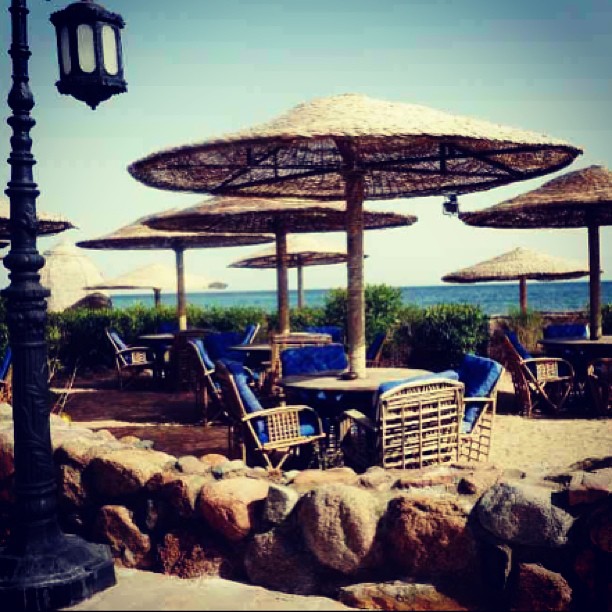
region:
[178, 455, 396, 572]
the wall is rocks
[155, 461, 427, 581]
the rocks are grey and red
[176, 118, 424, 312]
these are umbrellas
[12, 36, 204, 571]
this is a light post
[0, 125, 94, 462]
the light post is steel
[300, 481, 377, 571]
boulder in wall by ocean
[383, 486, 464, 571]
boulder in wall by ocean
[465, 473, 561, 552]
boulder in wall by ocean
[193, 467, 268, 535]
boulder in wall by ocean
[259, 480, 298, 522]
boulder in wall by ocean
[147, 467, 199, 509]
boulder in wall by ocean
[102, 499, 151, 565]
boulder in wall by ocean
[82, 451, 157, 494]
boulder in wall by ocean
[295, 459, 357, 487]
boulder in wall by ocean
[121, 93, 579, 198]
a large thatched umbrella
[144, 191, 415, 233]
a large thatched umbrella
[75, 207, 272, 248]
a large thatched umbrella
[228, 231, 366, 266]
a large thatched umbrella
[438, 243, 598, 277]
a large thatched umbrella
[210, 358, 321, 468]
a blue cushioned patio chair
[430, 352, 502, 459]
a blue cushioned patio chair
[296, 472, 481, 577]
rocks in the wall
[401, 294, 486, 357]
green bush in back of the table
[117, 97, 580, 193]
hay umbrella above the table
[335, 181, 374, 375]
pole of the umbrella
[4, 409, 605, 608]
sand is on ground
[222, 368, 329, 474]
chair has yellow cushion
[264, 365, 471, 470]
table is made with wood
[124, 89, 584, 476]
table has umbrella a on top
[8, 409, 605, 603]
rocks on sand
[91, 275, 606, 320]
water is blue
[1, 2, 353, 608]
black lamp pole on sand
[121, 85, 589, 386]
umbrella is a beige color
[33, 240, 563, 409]
trees in front of umbrella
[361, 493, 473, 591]
rock is red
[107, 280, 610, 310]
blue water making up the ocean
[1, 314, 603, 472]
wicker chairs with blue cushions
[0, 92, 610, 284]
wooven sun umbrellas covering tables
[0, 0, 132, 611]
a black metal pole with octagonal lamp attached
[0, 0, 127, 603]
ornate light pole and lamp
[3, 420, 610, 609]
low rock wall around beach dinning area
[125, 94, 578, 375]
woven shade umbrella over table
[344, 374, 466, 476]
rattan chair with blue cushion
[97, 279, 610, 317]
calm blue green sea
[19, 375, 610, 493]
sandy dinning area at sea side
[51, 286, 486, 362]
hedges edging sandy dinning area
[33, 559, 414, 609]
sidewalk outside of sandy dinning area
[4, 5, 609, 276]
slightly hazy blue sky over sea